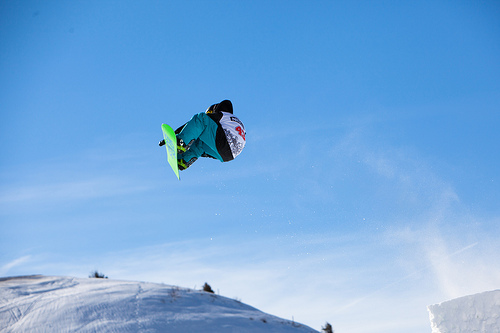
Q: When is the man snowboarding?
A: Sunny cold day.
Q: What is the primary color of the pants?
A: Blue.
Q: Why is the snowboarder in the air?
A: Jumping trick.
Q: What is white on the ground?
A: Snow.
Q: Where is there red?
A: Back of coat.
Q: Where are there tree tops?
A: Behind hill.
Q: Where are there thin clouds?
A: Low in sky.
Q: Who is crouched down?
A: Snowboarder.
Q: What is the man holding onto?
A: Board.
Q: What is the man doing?
A: Jumping.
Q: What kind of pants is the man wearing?
A: Ski.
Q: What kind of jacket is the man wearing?
A: White.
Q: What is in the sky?
A: Clouds.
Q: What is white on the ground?
A: Snow.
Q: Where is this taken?
A: Outside in the snow.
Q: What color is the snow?
A: White.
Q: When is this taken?
A: During the daytime.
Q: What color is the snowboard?
A: Green.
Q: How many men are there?
A: One.